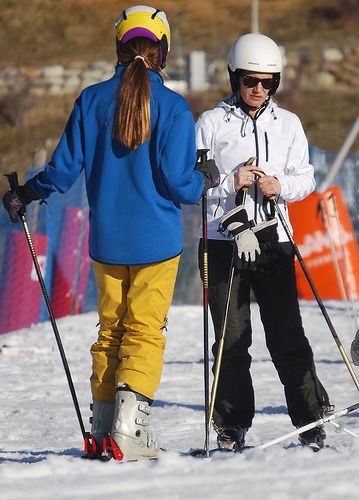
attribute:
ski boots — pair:
[206, 415, 334, 453]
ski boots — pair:
[78, 385, 167, 468]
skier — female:
[2, 5, 219, 461]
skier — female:
[193, 33, 329, 450]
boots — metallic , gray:
[85, 393, 164, 472]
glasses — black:
[231, 75, 303, 95]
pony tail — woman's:
[108, 38, 159, 165]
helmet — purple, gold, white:
[108, 5, 172, 69]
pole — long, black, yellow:
[226, 161, 325, 309]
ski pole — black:
[197, 146, 210, 458]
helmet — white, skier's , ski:
[226, 31, 283, 101]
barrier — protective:
[27, 218, 92, 276]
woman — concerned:
[189, 26, 340, 457]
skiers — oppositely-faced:
[30, 2, 315, 456]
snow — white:
[4, 304, 356, 494]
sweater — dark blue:
[23, 65, 200, 267]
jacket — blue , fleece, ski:
[23, 63, 213, 267]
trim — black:
[87, 247, 184, 264]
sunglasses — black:
[236, 68, 277, 97]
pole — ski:
[3, 165, 118, 449]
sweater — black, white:
[195, 72, 290, 214]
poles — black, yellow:
[219, 171, 353, 377]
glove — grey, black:
[213, 204, 263, 262]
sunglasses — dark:
[239, 75, 282, 90]